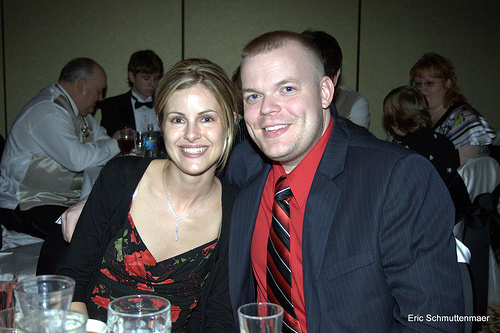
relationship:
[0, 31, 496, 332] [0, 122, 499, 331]
people at banquet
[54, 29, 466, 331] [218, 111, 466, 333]
man in clothes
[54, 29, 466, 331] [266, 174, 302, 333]
man wears tie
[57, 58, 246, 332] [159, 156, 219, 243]
woman wears necklace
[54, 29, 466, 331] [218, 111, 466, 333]
man wears clothes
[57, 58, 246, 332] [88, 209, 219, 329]
woman wears dress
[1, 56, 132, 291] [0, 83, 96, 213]
man wears vest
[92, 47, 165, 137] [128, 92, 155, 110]
boy wears bowtie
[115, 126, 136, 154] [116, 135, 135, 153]
glass has wine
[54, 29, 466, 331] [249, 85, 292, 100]
man has eyes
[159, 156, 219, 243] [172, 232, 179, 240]
necklace has diamond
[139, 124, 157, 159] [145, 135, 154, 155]
bottle has water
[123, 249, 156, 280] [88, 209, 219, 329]
rose on dress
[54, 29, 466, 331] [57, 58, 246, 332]
man with woman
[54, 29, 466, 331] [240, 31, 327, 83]
man has hair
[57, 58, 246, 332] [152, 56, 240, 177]
woman has hair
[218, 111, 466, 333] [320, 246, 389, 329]
clothes has pocket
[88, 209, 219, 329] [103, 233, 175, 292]
dress has flowers